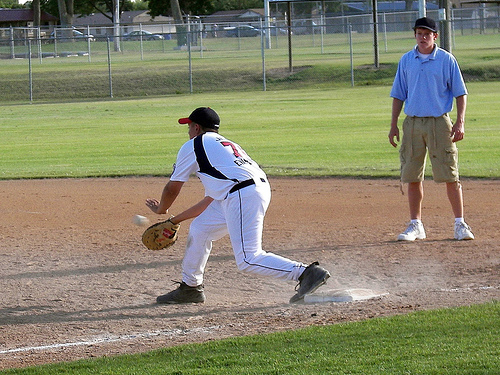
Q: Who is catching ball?
A: Player.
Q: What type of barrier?
A: Fence.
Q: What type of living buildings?
A: Homes.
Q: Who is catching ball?
A: Player.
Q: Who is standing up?
A: The man.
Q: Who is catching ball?
A: Player.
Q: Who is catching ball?
A: Player.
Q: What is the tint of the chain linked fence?
A: Grey.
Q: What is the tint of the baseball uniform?
A: Black, white and red.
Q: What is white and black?
A: Baseball uniform.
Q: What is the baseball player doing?
A: Catching a ball.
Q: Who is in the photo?
A: Two boys.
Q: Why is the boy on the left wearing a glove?
A: He's playing baseball.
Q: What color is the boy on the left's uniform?
A: White.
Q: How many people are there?
A: Two.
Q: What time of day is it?
A: Afternoon.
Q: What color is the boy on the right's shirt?
A: Blue.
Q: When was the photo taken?
A: Daytime.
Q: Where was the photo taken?
A: A baseball field.